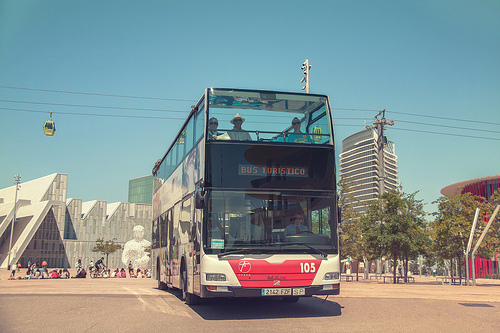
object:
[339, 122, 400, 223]
building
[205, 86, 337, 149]
window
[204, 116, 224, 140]
person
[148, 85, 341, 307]
bus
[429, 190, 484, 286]
tree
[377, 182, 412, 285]
trees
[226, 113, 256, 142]
man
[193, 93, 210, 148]
window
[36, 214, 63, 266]
wall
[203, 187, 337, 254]
window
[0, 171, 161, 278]
buldings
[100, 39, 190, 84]
sky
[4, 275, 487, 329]
road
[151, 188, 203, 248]
window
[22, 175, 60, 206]
wall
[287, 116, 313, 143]
person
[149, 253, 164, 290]
tire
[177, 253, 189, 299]
tire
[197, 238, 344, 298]
bumper